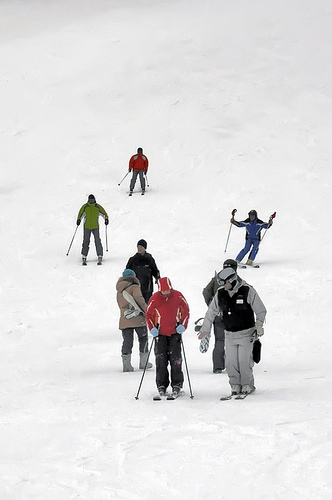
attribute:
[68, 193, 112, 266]
person — skiing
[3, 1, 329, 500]
snow — white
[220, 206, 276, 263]
person — skiing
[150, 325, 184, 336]
gloves — blue, light blue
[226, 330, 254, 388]
pants — grey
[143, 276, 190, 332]
sweater — red, hooded, white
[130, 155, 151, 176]
sweater — red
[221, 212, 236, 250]
ski pole — here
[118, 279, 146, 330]
coat — grey, brown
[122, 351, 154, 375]
boots — grey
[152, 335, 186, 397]
pants — black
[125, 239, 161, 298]
man — looking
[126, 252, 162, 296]
outfit — dark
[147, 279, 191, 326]
stripes — white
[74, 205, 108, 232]
jacket — green, grey